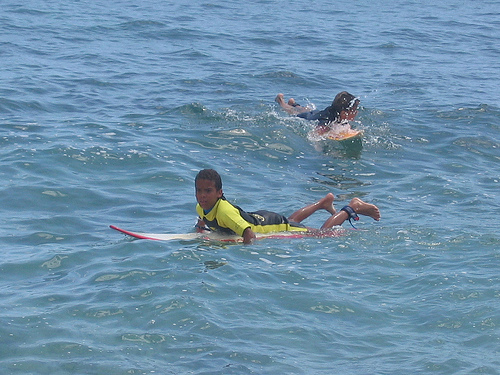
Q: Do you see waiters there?
A: No, there are no waiters.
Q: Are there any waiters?
A: No, there are no waiters.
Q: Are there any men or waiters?
A: No, there are no waiters or men.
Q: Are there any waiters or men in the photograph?
A: No, there are no waiters or men.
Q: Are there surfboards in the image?
A: Yes, there is a surfboard.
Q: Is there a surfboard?
A: Yes, there is a surfboard.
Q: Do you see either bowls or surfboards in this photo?
A: Yes, there is a surfboard.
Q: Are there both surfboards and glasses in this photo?
A: No, there is a surfboard but no glasses.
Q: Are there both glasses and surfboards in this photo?
A: No, there is a surfboard but no glasses.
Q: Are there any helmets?
A: No, there are no helmets.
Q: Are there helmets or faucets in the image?
A: No, there are no helmets or faucets.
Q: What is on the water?
A: The surfboard is on the water.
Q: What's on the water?
A: The surfboard is on the water.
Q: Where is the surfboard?
A: The surfboard is on the water.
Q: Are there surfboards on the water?
A: Yes, there is a surfboard on the water.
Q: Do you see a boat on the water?
A: No, there is a surfboard on the water.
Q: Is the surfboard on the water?
A: Yes, the surfboard is on the water.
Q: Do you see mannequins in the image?
A: No, there are no mannequins.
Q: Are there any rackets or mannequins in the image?
A: No, there are no mannequins or rackets.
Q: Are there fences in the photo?
A: No, there are no fences.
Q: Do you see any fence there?
A: No, there are no fences.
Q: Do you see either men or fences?
A: No, there are no fences or men.